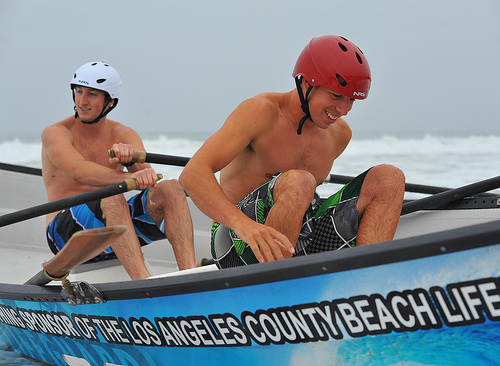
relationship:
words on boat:
[0, 279, 499, 348] [1, 161, 499, 365]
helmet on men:
[291, 37, 372, 103] [176, 30, 409, 272]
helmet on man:
[69, 62, 122, 102] [41, 62, 198, 281]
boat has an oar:
[1, 161, 499, 365] [109, 148, 454, 196]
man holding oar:
[41, 62, 198, 281] [109, 148, 454, 196]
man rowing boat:
[41, 62, 198, 281] [1, 161, 499, 365]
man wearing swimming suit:
[41, 62, 198, 281] [47, 187, 170, 264]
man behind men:
[41, 62, 198, 281] [176, 30, 409, 272]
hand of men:
[235, 218, 294, 263] [176, 30, 409, 272]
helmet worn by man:
[69, 62, 122, 102] [41, 62, 198, 281]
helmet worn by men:
[291, 37, 372, 103] [176, 30, 409, 272]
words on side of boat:
[0, 279, 499, 348] [1, 161, 499, 365]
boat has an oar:
[1, 161, 499, 365] [0, 172, 162, 228]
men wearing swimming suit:
[176, 30, 409, 272] [210, 165, 370, 269]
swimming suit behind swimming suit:
[47, 187, 170, 264] [210, 165, 370, 269]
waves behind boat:
[1, 132, 499, 195] [1, 161, 499, 365]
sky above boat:
[1, 0, 499, 129] [1, 161, 499, 365]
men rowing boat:
[39, 35, 406, 281] [1, 161, 499, 365]